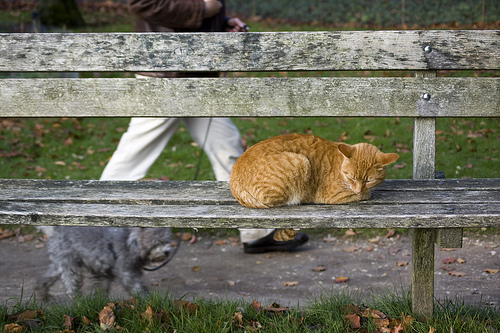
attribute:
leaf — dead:
[94, 301, 120, 331]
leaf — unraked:
[51, 157, 68, 169]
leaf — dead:
[341, 309, 365, 332]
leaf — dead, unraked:
[230, 311, 248, 331]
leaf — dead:
[225, 275, 241, 288]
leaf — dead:
[449, 269, 467, 278]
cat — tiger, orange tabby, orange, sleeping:
[233, 130, 395, 213]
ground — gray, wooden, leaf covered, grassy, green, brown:
[0, 32, 499, 322]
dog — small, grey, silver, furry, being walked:
[29, 220, 173, 308]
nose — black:
[163, 249, 170, 257]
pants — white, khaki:
[93, 73, 282, 249]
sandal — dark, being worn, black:
[241, 227, 310, 255]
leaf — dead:
[34, 122, 44, 129]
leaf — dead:
[393, 160, 408, 171]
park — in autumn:
[1, 2, 499, 330]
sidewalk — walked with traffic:
[1, 224, 497, 319]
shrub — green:
[223, 0, 498, 32]